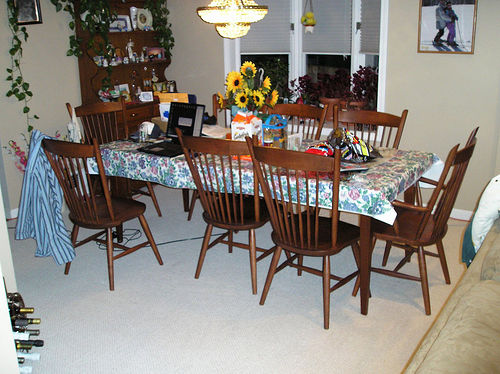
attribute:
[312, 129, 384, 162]
bags — red, black, chips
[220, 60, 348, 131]
sunflowers — yellow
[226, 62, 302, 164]
basket — hanging, fruit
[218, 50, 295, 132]
daisies — bouquet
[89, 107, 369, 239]
table — relatively long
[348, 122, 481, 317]
wooden chair — brown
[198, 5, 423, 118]
window — paned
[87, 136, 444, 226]
tablecloth — white, flower patterned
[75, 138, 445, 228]
table cloth — flower print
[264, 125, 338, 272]
chair — brown, runged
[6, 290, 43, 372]
bottles — alcohol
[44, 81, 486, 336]
table — wooden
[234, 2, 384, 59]
blinds — half closed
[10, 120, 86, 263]
shirt — blue, striped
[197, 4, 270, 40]
light — brightly lit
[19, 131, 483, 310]
chairs — eight